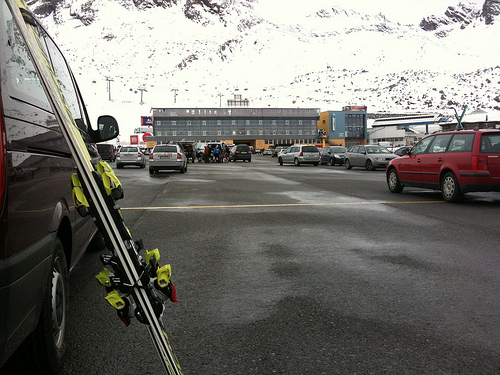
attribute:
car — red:
[383, 122, 499, 203]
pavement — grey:
[83, 161, 483, 373]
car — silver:
[274, 137, 323, 168]